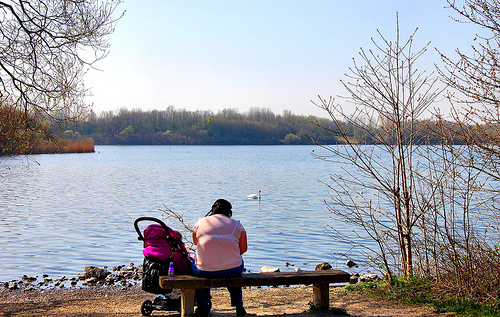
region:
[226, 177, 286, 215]
White swan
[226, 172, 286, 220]
White swan swimming in large pond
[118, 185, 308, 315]
Woman sitting on stone bench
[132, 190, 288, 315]
Woman sitting next to pink and black stroller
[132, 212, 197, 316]
Pink and black baby stroller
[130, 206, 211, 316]
Pink and black stroller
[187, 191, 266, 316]
Woman with visable bra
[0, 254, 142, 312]
Rocky shoreline of pond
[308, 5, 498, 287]
Barren tree's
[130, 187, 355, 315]
Woman in pink shirt and jeans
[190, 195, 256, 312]
Woman sitting on bench.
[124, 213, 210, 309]
Stroller next to woman at park.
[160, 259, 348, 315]
Wooden park bench.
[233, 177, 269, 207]
White swan in water.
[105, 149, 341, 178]
Calm blue body of water.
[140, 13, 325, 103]
Weather is clear blue skies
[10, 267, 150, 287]
Rocks at the shore of the water.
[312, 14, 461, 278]
Tree without any leaves.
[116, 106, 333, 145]
Green forest in the background.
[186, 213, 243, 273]
White shirt with bra line showing.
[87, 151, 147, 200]
the water is blue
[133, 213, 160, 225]
handle on the stroller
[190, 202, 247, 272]
a women is sitting on the bench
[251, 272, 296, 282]
the bench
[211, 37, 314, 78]
the sky is clear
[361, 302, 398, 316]
dirt on the ground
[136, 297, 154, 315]
wheel on the stroller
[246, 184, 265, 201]
a duck in the water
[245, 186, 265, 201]
a white duck in the water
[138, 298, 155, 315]
black wheel of a stroller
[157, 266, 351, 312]
long wooden bench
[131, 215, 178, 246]
black handle of a stroller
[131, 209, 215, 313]
pink and black stroller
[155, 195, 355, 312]
woman sitting on a bench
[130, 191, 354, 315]
woman sitting on a bench with a stroller in front of her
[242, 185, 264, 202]
a white swan swimming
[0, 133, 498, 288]
clear blue waters of a lake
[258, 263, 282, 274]
white rock in the water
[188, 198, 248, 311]
a woman is sitting on a bench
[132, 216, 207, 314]
a stroller is pink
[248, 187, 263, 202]
a bird is in water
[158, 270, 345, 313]
a small stone bench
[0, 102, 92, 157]
land near water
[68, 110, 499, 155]
the shore is covered with bushes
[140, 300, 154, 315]
wheel on a stroller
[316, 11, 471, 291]
a grouping of leafless trees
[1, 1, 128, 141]
leafless branches on a tree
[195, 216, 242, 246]
a woman's bra straps